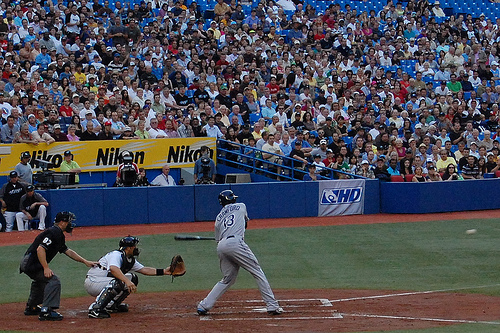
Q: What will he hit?
A: The ball.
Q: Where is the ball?
A: In the air.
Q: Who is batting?
A: The player.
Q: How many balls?
A: 1.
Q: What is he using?
A: Bat.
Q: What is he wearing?
A: Helmet.